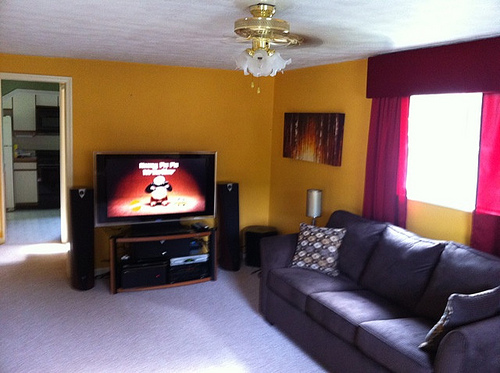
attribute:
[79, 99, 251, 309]
tv stand —  brown and black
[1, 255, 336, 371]
carpet — White 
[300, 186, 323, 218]
silver lamp — tall, thin  and silver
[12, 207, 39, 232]
floor — kitchen, tiled, white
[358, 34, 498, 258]
curtains — red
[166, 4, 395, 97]
ceiling fan — gold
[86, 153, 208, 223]
screen — flat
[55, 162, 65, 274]
framed — white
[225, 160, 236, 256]
speaker — tall and black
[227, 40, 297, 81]
globe — large